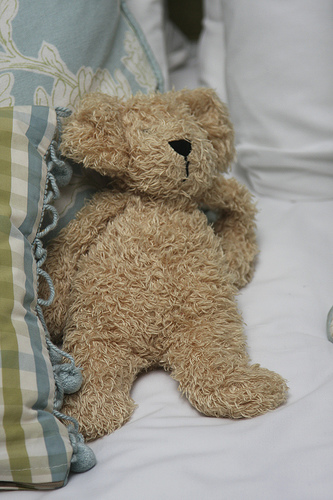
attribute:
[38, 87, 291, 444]
teddy bear — soft, cream colored, brown, light brown, furry, tan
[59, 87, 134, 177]
ear — floppy, big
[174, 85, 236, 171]
ear — soft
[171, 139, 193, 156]
nose — black, soft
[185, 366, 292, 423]
paw — soft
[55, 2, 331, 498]
sheet — white, clean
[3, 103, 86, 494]
pillow — green accented, white, blue, green checkered, striped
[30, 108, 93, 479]
fringe — blue, baby blue, yarn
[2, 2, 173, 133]
coverlet — floral designed, blue, white, blue green, blue patterned, beige, floral, flower printed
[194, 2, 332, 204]
pillow — white, creased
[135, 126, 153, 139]
eye — barely visable